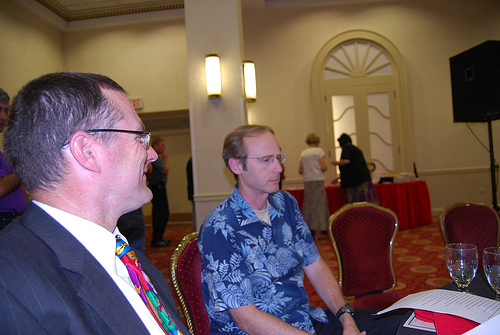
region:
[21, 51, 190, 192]
Man wearing black glasses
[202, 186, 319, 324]
Man wearing blue shirt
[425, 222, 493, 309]
Empty glass of water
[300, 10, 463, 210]
Large arched doorway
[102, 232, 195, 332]
Man wearing colorful tie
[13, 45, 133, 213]
Man has gray and black hair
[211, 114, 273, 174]
Man has light brown hair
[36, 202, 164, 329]
Man has white shirt under a jacket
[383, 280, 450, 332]
Printed paper on table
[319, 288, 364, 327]
Man wearing black watch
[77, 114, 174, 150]
black eye glasses on man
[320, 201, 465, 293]
red and yellow ornate carpet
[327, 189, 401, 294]
red ornate chair with gold frame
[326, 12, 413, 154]
white arched doorway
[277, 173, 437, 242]
red table cloth draped over table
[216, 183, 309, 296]
floral pattern on blue shirt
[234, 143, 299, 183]
eye glasses on blonde man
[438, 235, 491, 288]
mostly empty white wine glasses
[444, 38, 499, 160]
black p.a. speaker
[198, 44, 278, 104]
illuminated light on white pillar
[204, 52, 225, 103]
a wall sconce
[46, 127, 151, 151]
a man's eyeglasses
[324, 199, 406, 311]
a red and gold chair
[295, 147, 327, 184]
a woman's white short sleeve shirt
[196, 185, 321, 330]
a man's blue short sleeve shirt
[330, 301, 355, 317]
a man's black wristwatch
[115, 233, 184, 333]
a colorful tie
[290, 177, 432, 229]
a long red tablecloth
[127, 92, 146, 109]
part of a red and white exit sign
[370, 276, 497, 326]
a white sheet of paper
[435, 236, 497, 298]
empty glasses on table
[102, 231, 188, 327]
man wearing multi colored tie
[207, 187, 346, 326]
man wearing blue flowered shirt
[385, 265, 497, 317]
paper laying on table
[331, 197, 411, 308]
empty red chair at table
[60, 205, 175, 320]
man wearing white collared shirt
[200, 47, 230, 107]
light hanging on wall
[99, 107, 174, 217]
man with glasses smiling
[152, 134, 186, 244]
man standing in line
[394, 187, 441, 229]
red table cloth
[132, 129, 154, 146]
Man wearing eyeglasses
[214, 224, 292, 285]
Man wearing light blue shirt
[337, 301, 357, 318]
Man wearing a watch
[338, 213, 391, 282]
Red chair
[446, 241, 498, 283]
two glasses on the table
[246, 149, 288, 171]
Man wearing eyeglasses.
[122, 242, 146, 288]
Man wearing a tie.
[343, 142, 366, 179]
Women wearing a black shirt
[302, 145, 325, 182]
Women wearing a white shirt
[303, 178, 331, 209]
Women wearing a tanned skirt